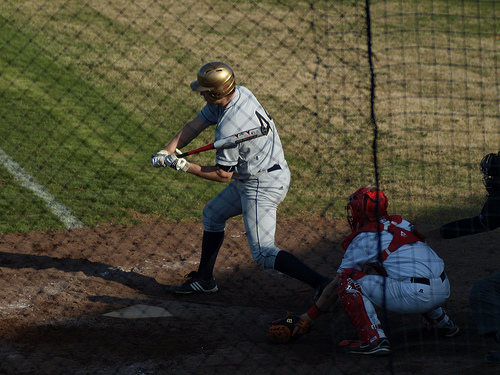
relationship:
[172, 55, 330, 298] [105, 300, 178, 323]
batter at plate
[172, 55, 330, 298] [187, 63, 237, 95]
batter has helmet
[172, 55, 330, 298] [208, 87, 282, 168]
batter has shirt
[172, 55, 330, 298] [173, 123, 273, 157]
batter swinging bat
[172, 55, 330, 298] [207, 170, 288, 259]
batter has pants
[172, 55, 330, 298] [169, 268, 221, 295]
batter has shoe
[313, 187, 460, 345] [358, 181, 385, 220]
catcher has helmet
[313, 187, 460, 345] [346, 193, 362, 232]
catcher has guard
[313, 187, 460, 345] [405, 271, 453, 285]
catcher has belt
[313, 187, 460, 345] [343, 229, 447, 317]
catcher has outfit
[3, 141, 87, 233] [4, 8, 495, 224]
line on top of grass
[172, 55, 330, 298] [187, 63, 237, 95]
batter with helmet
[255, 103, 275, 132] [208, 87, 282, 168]
44 on back of shirt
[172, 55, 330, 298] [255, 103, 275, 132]
batter with 44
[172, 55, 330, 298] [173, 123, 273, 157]
batter with bat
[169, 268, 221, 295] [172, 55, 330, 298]
shoe of batter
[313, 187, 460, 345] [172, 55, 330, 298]
catcher behind batter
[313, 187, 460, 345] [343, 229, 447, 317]
catcher with uniform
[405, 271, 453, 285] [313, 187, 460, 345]
belt on waist of catcher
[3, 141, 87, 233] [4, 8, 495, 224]
line painted on field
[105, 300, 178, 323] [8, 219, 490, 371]
plate on top of dirt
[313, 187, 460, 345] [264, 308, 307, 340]
catcher wearing mitt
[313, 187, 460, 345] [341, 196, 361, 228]
catcher wearing mask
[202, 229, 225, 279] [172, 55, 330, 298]
sock on leg of batter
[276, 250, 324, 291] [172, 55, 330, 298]
sock on leg of batter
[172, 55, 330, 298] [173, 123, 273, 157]
batter holding bat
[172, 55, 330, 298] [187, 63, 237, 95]
batter wearing helmet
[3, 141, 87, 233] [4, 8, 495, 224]
line on field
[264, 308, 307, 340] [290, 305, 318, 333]
mitt in left hand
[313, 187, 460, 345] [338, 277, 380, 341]
catcher wearing pads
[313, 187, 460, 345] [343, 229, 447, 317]
catcher wearing outfit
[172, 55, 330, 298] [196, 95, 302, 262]
batter wearing uniform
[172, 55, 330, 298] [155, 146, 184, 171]
batter wearing gloves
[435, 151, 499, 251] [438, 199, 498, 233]
umpire with jacket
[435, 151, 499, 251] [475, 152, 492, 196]
umpire with mask